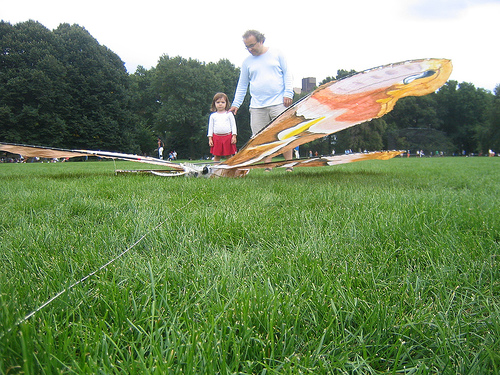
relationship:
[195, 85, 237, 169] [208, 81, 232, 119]
girl has hair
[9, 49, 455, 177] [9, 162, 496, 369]
kite on grass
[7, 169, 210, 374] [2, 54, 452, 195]
string attached to kite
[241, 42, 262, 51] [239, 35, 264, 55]
glasses on face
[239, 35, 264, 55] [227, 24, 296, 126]
face of man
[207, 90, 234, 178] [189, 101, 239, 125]
girl wearing shirt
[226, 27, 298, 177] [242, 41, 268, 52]
man wearing glasses